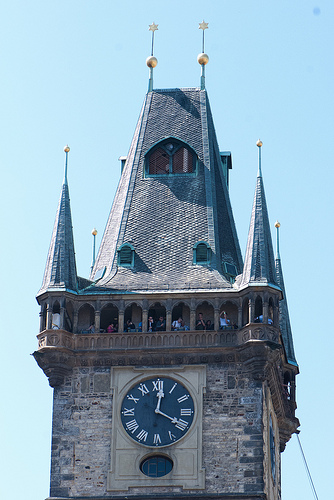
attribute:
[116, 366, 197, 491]
clock — ANALOG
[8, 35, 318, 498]
tower — CLOCK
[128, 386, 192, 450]
face — CLOCK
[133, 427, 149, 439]
details — GOLD, BLACK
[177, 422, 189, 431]
numerals — ROMAN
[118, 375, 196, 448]
face — CLOCK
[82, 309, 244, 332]
people — GROUP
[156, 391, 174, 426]
hand — HOUR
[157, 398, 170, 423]
hand — GOLD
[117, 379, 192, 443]
face — CLOCK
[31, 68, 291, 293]
shingles — BLUE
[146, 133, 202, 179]
window — ARCHED, OPEN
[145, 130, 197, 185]
window — OPEN, ARCHED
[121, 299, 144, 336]
window — open, arched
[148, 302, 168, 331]
window — arched, open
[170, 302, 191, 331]
window — open, arched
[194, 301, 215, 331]
window — arched, open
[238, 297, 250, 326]
window — open, arched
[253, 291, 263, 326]
window — arched, open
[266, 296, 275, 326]
window — open, arched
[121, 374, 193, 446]
face — black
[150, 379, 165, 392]
number — white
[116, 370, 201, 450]
clock — black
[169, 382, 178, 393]
number — white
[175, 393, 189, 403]
number — white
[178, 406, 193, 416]
number — white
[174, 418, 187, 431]
number — white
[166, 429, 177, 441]
number — white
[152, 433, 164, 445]
number — white 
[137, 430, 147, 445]
number — white 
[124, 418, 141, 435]
number — white 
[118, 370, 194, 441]
clock — large 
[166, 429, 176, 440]
numeral — roman 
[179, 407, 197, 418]
numeral — roman 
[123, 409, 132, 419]
numeral — roman 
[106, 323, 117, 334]
shirt — pink 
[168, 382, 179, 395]
numeral — roman 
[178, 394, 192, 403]
numeral — roman 